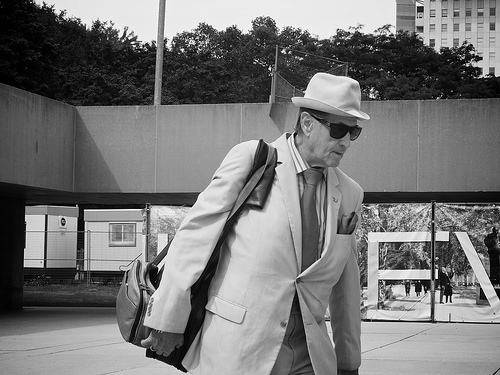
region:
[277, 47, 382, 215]
a man wearing sunglasses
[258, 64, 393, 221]
a man wearing a hat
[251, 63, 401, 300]
a man wearing a tie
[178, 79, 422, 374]
a man in a suit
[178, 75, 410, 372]
a man wearing a jacket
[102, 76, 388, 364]
a man holding a bag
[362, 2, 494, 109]
a tall building with lots of windows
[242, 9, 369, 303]
a man wearing a striped shirt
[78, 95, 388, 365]
a man wearing a ring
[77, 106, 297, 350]
a bag over his shoulder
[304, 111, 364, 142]
black sunglasses on face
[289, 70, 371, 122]
white hat on head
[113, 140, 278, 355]
a man's side bag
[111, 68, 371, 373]
a man in a white suit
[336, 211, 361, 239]
part of tissue out of pocket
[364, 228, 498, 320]
giant letters on wall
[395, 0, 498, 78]
tall building in background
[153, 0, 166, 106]
tall grey pole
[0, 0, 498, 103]
tops of leafy trees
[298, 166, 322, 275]
a long tie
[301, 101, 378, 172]
man with black shades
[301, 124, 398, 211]
man with black shades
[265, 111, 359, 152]
man with black shades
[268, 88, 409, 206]
man with black shades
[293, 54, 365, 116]
man wears light hat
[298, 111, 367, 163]
man wears dark glasses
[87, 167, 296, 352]
man carries bag on shoulder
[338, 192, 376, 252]
man has kerchief in breast pocket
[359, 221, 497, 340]
letters outside window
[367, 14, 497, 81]
tall light colored building behind man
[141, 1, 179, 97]
tall pole left of man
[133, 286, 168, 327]
buttons on jacket sleeve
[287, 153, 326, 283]
man wears striped shirt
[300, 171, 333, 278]
man wears solid color necktie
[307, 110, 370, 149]
Sunglasses on the man's face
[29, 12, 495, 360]
The photo is in black and white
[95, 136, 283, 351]
Shoulder bag on the man's shoulder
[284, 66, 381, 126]
Fedora on the man's head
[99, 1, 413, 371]
The man is wearing a suit and tie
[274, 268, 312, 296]
One button is buttoned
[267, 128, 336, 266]
The man's shirt is striped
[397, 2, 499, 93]
Tall building in the background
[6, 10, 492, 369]
Photo taken during the day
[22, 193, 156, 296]
White trailers to the left